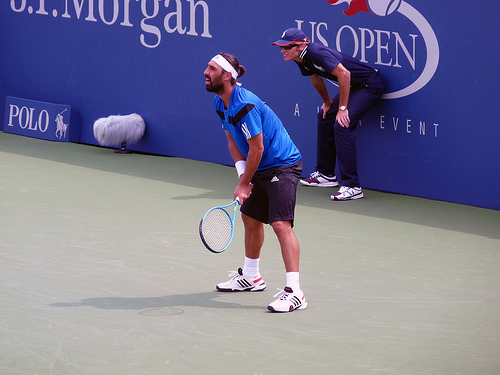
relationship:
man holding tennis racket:
[175, 43, 310, 332] [188, 196, 250, 249]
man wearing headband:
[175, 43, 310, 332] [209, 44, 262, 88]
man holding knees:
[175, 43, 310, 332] [239, 201, 305, 236]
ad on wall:
[2, 93, 80, 145] [445, 30, 491, 50]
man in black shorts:
[175, 43, 310, 332] [245, 164, 307, 229]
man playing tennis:
[175, 43, 310, 332] [148, 83, 151, 85]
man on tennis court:
[197, 50, 309, 313] [55, 260, 131, 288]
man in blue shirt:
[175, 43, 310, 332] [308, 36, 365, 96]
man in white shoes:
[175, 43, 310, 332] [227, 265, 311, 319]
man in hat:
[175, 43, 310, 332] [272, 29, 313, 50]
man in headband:
[175, 43, 310, 332] [209, 44, 262, 88]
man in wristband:
[175, 43, 310, 332] [229, 160, 254, 182]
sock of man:
[241, 254, 263, 276] [175, 43, 310, 332]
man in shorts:
[175, 43, 310, 332] [245, 164, 307, 229]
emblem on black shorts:
[267, 169, 283, 189] [245, 164, 307, 229]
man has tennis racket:
[175, 43, 310, 332] [188, 196, 250, 249]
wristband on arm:
[229, 160, 254, 182] [233, 154, 256, 187]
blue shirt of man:
[308, 36, 365, 96] [175, 43, 310, 332]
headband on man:
[209, 44, 262, 88] [175, 43, 310, 332]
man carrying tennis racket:
[175, 43, 310, 332] [188, 196, 250, 249]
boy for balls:
[273, 33, 380, 211] [421, 38, 428, 44]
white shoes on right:
[227, 265, 311, 319] [221, 268, 287, 287]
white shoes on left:
[227, 265, 311, 319] [270, 287, 318, 314]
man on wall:
[175, 43, 310, 332] [445, 30, 491, 50]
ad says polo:
[2, 93, 80, 145] [12, 106, 38, 127]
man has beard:
[175, 43, 310, 332] [204, 81, 229, 92]